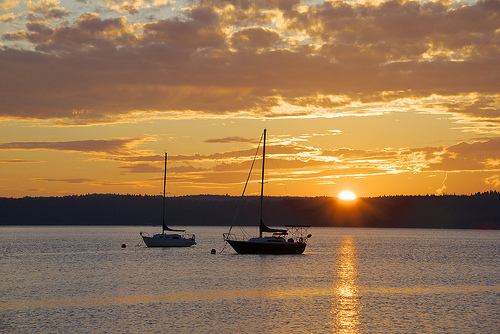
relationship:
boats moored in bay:
[224, 127, 311, 253] [1, 200, 499, 333]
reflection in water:
[330, 231, 376, 333] [0, 224, 500, 331]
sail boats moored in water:
[139, 152, 197, 248] [1, 255, 500, 332]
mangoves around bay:
[313, 194, 500, 228] [1, 200, 499, 333]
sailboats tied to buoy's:
[224, 127, 311, 253] [209, 245, 220, 256]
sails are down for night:
[260, 222, 290, 235] [0, 2, 499, 331]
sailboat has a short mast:
[139, 152, 197, 248] [161, 152, 171, 234]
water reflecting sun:
[0, 224, 500, 331] [338, 187, 358, 204]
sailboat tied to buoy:
[224, 127, 311, 253] [209, 245, 220, 256]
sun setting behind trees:
[338, 187, 358, 204] [313, 194, 500, 228]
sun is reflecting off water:
[329, 188, 366, 332] [0, 224, 500, 331]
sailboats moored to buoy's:
[224, 127, 311, 253] [209, 245, 220, 256]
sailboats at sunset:
[224, 127, 311, 253] [1, 1, 499, 198]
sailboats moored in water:
[139, 128, 313, 255] [1, 255, 500, 332]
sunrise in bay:
[0, 2, 499, 331] [1, 200, 499, 333]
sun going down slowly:
[338, 187, 358, 204] [1, 1, 499, 198]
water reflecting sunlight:
[0, 224, 500, 331] [320, 228, 363, 333]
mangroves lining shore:
[277, 190, 499, 228] [306, 207, 500, 230]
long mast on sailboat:
[256, 128, 269, 240] [224, 127, 311, 253]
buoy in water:
[209, 245, 220, 256] [1, 255, 500, 332]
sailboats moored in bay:
[139, 128, 313, 255] [1, 200, 499, 333]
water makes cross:
[0, 224, 500, 331] [291, 255, 387, 308]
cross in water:
[291, 255, 387, 308] [208, 243, 368, 331]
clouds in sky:
[158, 35, 363, 100] [1, 1, 499, 198]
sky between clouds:
[1, 1, 499, 198] [202, 78, 385, 120]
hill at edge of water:
[369, 192, 479, 216] [187, 260, 401, 329]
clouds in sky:
[141, 40, 394, 82] [1, 1, 499, 198]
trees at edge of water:
[2, 194, 142, 228] [341, 236, 467, 330]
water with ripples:
[194, 267, 375, 309] [1, 255, 500, 332]